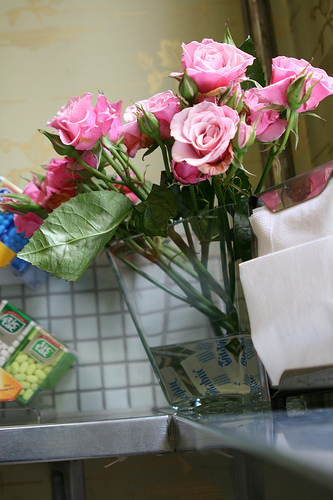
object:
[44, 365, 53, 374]
tic tac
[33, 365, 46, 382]
tic tac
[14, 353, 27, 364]
tic tac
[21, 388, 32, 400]
tic tac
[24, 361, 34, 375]
tic tac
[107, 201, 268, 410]
glass vase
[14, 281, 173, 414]
ceramic tile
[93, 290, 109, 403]
grout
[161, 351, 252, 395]
flower food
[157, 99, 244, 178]
flower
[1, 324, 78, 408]
tic tacs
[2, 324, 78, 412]
container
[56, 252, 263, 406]
countertop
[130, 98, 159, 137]
rose bud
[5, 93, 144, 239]
pink flown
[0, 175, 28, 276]
container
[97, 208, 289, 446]
vase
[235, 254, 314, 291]
paper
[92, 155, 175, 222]
stem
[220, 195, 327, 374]
towels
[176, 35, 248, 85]
flower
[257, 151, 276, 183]
stem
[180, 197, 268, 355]
stem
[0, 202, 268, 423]
floor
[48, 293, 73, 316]
tile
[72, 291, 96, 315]
tile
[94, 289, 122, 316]
tile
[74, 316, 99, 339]
tile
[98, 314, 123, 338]
tile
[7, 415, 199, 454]
table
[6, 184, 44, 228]
pink flower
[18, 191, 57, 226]
green stem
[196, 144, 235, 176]
browned petal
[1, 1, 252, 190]
cream wall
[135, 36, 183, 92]
gold accents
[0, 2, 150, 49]
gold accents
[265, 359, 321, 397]
rack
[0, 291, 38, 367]
container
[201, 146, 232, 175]
petal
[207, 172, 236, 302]
stem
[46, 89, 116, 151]
flower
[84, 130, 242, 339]
stem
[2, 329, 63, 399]
tacs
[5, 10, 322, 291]
flown